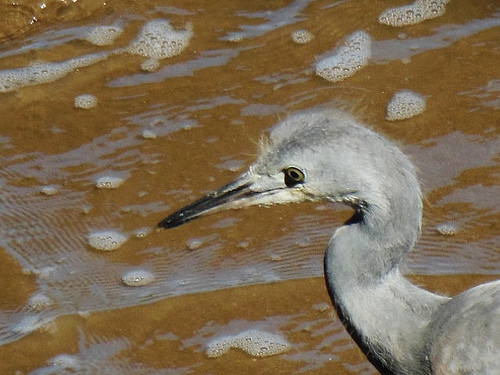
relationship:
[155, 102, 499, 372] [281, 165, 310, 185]
bird has eye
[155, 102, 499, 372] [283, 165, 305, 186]
bird has eye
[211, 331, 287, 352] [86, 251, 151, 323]
foam on beach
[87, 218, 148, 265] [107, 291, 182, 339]
foam on beach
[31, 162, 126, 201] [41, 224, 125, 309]
foam on beach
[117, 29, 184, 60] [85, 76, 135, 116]
foam on beach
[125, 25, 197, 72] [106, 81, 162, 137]
foam on beach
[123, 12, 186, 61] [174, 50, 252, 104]
foam on beach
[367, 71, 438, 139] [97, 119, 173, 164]
foam on beach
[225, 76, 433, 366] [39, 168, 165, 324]
bird in front of water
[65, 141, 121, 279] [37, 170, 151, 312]
bubbles on surface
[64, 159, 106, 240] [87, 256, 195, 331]
sand under water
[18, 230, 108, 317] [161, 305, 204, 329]
lines in water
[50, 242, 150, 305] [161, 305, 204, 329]
grids in water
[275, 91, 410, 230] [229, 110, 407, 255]
feathers on head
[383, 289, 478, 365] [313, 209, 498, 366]
markings on body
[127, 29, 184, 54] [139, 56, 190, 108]
bubbles in water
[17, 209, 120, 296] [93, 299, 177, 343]
pattern in water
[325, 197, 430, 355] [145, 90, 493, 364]
neck of white and gray bird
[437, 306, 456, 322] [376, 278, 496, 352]
gray and white heron feathers